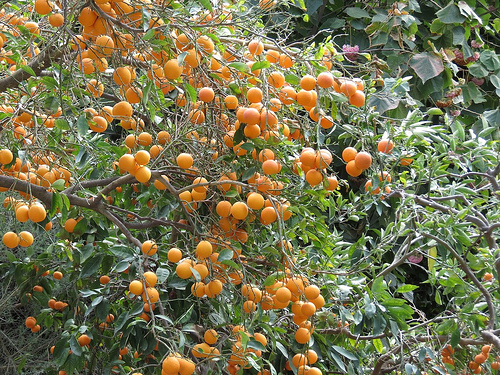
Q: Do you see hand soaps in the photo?
A: No, there are no hand soaps.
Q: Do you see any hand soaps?
A: No, there are no hand soaps.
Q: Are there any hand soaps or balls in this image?
A: No, there are no hand soaps or balls.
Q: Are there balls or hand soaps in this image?
A: No, there are no hand soaps or balls.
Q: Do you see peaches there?
A: Yes, there is a peach.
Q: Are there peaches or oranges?
A: Yes, there is a peach.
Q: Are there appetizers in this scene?
A: No, there are no appetizers.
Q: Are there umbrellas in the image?
A: No, there are no umbrellas.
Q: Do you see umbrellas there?
A: No, there are no umbrellas.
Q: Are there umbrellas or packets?
A: No, there are no umbrellas or packets.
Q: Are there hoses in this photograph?
A: No, there are no hoses.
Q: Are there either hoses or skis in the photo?
A: No, there are no hoses or skis.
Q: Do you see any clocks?
A: No, there are no clocks.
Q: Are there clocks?
A: No, there are no clocks.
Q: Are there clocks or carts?
A: No, there are no clocks or carts.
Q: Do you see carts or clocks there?
A: No, there are no clocks or carts.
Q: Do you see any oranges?
A: Yes, there are oranges.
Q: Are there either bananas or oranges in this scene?
A: Yes, there are oranges.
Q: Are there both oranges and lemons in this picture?
A: No, there are oranges but no lemons.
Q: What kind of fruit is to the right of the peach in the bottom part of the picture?
A: The fruits are oranges.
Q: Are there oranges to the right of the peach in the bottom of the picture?
A: Yes, there are oranges to the right of the peach.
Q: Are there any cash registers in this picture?
A: No, there are no cash registers.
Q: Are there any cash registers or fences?
A: No, there are no cash registers or fences.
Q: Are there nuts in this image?
A: No, there are no nuts.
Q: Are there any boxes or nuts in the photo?
A: No, there are no nuts or boxes.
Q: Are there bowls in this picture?
A: No, there are no bowls.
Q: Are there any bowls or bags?
A: No, there are no bowls or bags.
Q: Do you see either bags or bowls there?
A: No, there are no bowls or bags.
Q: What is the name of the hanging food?
A: The food is fruits.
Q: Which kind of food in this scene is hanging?
A: The food is fruits.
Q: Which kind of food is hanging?
A: The food is fruits.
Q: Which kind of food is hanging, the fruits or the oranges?
A: The fruits is hanging.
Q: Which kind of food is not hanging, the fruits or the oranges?
A: The oranges is not hanging.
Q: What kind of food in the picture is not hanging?
A: The food is oranges.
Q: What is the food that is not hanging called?
A: The food is oranges.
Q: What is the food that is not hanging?
A: The food is oranges.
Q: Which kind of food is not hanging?
A: The food is oranges.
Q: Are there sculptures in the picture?
A: No, there are no sculptures.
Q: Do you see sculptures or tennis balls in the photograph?
A: No, there are no sculptures or tennis balls.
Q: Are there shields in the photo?
A: No, there are no shields.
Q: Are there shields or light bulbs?
A: No, there are no shields or light bulbs.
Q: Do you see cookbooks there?
A: No, there are no cookbooks.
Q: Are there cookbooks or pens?
A: No, there are no cookbooks or pens.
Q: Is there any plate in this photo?
A: No, there are no plates.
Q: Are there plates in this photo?
A: No, there are no plates.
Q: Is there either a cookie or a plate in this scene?
A: No, there are no plates or cookies.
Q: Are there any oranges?
A: Yes, there are oranges.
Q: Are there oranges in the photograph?
A: Yes, there are oranges.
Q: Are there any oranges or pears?
A: Yes, there are oranges.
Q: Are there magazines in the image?
A: No, there are no magazines.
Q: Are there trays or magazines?
A: No, there are no magazines or trays.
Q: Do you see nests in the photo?
A: No, there are no nests.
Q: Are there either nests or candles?
A: No, there are no nests or candles.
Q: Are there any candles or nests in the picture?
A: No, there are no nests or candles.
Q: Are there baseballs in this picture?
A: No, there are no baseballs.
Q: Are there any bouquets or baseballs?
A: No, there are no baseballs or bouquets.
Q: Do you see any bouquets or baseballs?
A: No, there are no baseballs or bouquets.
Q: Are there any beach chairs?
A: No, there are no beach chairs.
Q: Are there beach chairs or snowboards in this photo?
A: No, there are no beach chairs or snowboards.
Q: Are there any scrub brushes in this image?
A: No, there are no scrub brushes.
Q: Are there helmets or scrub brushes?
A: No, there are no scrub brushes or helmets.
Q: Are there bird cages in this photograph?
A: No, there are no bird cages.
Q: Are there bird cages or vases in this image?
A: No, there are no bird cages or vases.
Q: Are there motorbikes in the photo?
A: No, there are no motorbikes.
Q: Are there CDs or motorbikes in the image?
A: No, there are no motorbikes or cds.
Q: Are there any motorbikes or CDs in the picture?
A: No, there are no motorbikes or cds.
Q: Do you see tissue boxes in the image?
A: No, there are no tissue boxes.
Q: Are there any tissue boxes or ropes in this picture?
A: No, there are no tissue boxes or ropes.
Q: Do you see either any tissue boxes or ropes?
A: No, there are no tissue boxes or ropes.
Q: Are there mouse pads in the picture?
A: No, there are no mouse pads.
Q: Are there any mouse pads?
A: No, there are no mouse pads.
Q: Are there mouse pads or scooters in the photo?
A: No, there are no mouse pads or scooters.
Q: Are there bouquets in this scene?
A: No, there are no bouquets.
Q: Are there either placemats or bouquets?
A: No, there are no bouquets or placemats.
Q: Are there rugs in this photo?
A: No, there are no rugs.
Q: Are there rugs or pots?
A: No, there are no rugs or pots.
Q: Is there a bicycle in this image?
A: No, there are no bicycles.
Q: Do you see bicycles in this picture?
A: No, there are no bicycles.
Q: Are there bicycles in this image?
A: No, there are no bicycles.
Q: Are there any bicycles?
A: No, there are no bicycles.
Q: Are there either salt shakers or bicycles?
A: No, there are no bicycles or salt shakers.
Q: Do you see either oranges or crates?
A: Yes, there are oranges.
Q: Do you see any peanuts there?
A: No, there are no peanuts.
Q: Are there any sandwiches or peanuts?
A: No, there are no peanuts or sandwiches.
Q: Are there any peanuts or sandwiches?
A: No, there are no peanuts or sandwiches.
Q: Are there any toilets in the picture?
A: No, there are no toilets.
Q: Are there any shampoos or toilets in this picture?
A: No, there are no toilets or shampoos.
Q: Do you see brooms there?
A: No, there are no brooms.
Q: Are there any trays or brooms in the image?
A: No, there are no brooms or trays.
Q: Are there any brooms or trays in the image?
A: No, there are no brooms or trays.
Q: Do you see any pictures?
A: No, there are no pictures.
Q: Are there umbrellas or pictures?
A: No, there are no pictures or umbrellas.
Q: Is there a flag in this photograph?
A: No, there are no flags.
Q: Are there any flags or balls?
A: No, there are no flags or balls.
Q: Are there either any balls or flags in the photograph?
A: No, there are no flags or balls.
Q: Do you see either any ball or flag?
A: No, there are no flags or balls.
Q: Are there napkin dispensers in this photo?
A: No, there are no napkin dispensers.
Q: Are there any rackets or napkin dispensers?
A: No, there are no napkin dispensers or rackets.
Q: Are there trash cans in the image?
A: No, there are no trash cans.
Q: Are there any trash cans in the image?
A: No, there are no trash cans.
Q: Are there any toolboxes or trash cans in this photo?
A: No, there are no trash cans or toolboxes.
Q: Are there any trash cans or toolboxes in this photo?
A: No, there are no trash cans or toolboxes.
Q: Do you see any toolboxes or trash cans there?
A: No, there are no trash cans or toolboxes.